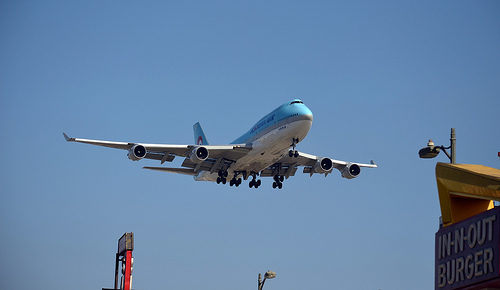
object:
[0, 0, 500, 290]
sky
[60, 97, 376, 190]
plane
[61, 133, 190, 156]
wing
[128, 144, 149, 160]
engine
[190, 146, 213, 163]
engine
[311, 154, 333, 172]
engine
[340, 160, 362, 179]
engine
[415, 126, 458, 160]
light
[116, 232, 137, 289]
isgn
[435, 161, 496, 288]
sign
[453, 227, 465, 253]
n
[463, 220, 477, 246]
letter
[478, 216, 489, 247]
letter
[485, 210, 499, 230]
letter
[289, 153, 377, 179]
wing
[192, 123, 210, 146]
tail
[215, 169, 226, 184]
wheel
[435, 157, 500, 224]
arrow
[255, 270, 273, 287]
light